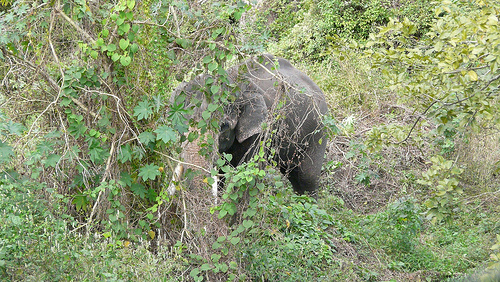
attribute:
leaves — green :
[70, 95, 160, 213]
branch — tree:
[100, 6, 225, 256]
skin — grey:
[270, 72, 309, 131]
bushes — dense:
[66, 45, 204, 218]